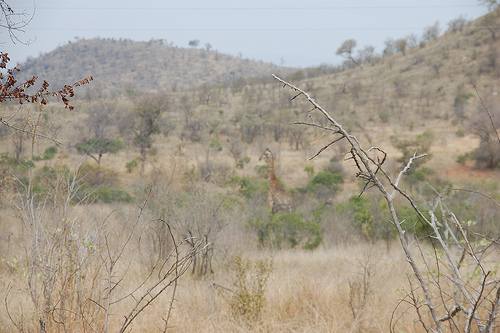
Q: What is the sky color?
A: Blue.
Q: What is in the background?
A: Hills.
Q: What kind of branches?
A: Dead.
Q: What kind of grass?
A: Dried.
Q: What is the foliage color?
A: Green.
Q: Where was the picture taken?
A: In a hilly landscape.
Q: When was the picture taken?
A: On a clear day.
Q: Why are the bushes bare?
A: Animals have fed on them.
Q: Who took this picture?
A: A landscape photographer.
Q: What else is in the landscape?
A: Green shrubs and trees.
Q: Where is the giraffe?
A: In the shrubs.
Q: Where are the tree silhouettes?
A: On the hilltops.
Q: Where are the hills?
A: Behind the giraffe.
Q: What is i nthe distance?
A: Mountain.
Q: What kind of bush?
A: Dry.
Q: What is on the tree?
A: Leaves.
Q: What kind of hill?
A: Rolling.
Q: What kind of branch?
A: Dead.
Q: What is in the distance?
A: Hill.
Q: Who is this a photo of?
A: A giraffe.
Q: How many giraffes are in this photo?
A: One.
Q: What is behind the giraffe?
A: Hills.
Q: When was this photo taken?
A: Daytime.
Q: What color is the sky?
A: Blue.